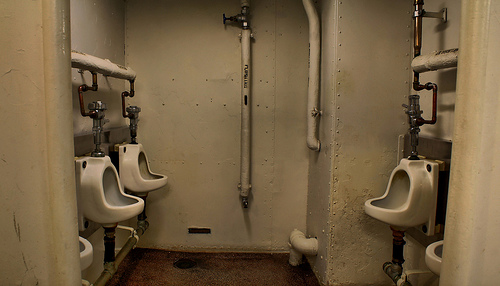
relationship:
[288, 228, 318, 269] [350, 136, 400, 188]
pipe on ground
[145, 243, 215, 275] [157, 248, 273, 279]
drain in floor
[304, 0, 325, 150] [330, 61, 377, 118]
pipe in wall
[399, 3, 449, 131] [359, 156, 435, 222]
pipe in toilet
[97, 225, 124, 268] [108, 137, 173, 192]
pipe in urinal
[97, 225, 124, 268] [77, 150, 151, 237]
pipe in urinal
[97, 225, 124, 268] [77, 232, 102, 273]
pipe in urinal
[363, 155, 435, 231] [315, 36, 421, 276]
urinal on waall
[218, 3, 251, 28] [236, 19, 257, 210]
handle on pipe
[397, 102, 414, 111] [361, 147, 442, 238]
flush handle on urinal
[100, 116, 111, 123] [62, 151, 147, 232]
flush handle on urinal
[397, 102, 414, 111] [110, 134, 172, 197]
flush handle on urinal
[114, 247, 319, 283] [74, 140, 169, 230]
dirty floor under urinal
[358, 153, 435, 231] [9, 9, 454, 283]
urinal in room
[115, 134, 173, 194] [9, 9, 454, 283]
urinal in room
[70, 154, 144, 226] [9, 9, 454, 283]
urinal in room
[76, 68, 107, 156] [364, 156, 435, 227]
pipes in urinal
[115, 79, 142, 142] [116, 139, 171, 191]
pipes in urinal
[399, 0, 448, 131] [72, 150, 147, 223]
pipe in urinal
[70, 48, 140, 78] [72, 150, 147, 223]
pipes in urinal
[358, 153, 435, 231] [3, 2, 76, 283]
urinal in wall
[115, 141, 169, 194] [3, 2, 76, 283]
urinal in wall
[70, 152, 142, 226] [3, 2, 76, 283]
urinal in wall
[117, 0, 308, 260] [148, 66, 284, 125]
wall with rivets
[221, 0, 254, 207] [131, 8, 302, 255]
pipe with wall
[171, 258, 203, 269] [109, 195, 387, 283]
drain in floor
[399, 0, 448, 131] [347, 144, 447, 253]
pipe running to urinal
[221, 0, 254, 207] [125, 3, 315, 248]
pipe on wall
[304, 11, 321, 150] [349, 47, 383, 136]
pipe attached to wall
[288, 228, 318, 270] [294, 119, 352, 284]
pipe attached to wall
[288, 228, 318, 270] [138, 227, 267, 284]
pipe attached to floor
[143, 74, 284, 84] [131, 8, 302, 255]
rivets on wall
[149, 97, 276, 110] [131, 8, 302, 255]
rivets on wall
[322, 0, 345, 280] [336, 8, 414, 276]
rivets on wall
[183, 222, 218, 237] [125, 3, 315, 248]
hole in wall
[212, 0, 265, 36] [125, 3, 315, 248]
valve on wall